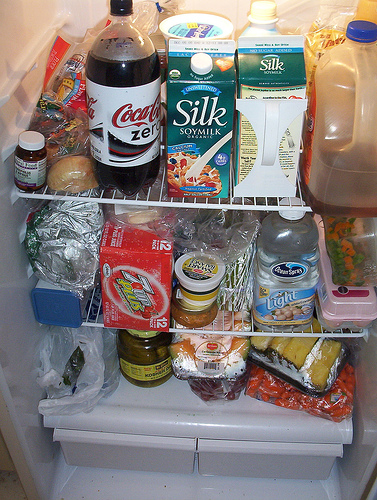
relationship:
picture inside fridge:
[1, 0, 372, 497] [1, 5, 375, 498]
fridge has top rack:
[1, 5, 375, 498] [12, 2, 376, 216]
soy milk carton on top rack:
[161, 33, 238, 208] [12, 2, 376, 216]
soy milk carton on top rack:
[233, 28, 310, 203] [12, 2, 376, 216]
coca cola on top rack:
[82, 0, 164, 197] [12, 2, 376, 216]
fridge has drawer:
[1, 5, 375, 498] [48, 427, 199, 483]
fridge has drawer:
[1, 5, 375, 498] [195, 432, 348, 485]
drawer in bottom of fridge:
[48, 427, 199, 483] [1, 5, 375, 498]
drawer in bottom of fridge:
[195, 432, 348, 485] [1, 5, 375, 498]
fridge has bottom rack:
[1, 5, 375, 498] [27, 324, 366, 449]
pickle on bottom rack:
[114, 327, 178, 392] [27, 324, 366, 449]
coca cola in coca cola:
[85, 47, 163, 196] [82, 0, 164, 197]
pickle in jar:
[114, 327, 178, 392] [114, 327, 176, 389]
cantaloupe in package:
[168, 339, 250, 376] [169, 331, 254, 387]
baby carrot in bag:
[336, 380, 355, 401] [244, 362, 359, 426]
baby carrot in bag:
[256, 385, 279, 401] [244, 362, 359, 426]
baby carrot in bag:
[256, 388, 272, 403] [244, 362, 359, 426]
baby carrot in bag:
[336, 371, 355, 401] [244, 362, 359, 426]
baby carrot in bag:
[270, 385, 285, 407] [244, 362, 359, 426]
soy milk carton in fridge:
[161, 33, 238, 208] [1, 5, 375, 498]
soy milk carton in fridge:
[233, 28, 310, 203] [1, 5, 375, 498]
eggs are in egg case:
[312, 216, 376, 332] [311, 213, 375, 337]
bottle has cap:
[11, 129, 50, 197] [16, 131, 49, 154]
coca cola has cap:
[82, 0, 164, 197] [109, 0, 136, 18]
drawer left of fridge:
[48, 427, 199, 483] [1, 5, 375, 498]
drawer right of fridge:
[195, 432, 348, 485] [1, 5, 375, 498]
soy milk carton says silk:
[161, 33, 238, 208] [172, 93, 233, 130]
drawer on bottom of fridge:
[48, 427, 199, 483] [1, 5, 375, 498]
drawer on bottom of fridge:
[195, 432, 348, 485] [1, 5, 375, 498]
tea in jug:
[299, 163, 376, 223] [298, 16, 376, 221]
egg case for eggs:
[311, 213, 375, 337] [312, 216, 376, 332]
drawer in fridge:
[48, 427, 199, 483] [1, 5, 375, 498]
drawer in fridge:
[195, 432, 348, 485] [1, 5, 375, 498]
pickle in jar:
[114, 327, 173, 391] [114, 327, 176, 389]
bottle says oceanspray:
[247, 202, 320, 335] [270, 263, 310, 279]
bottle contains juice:
[247, 202, 320, 335] [252, 250, 321, 334]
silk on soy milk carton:
[172, 93, 233, 130] [161, 33, 238, 208]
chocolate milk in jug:
[299, 163, 376, 223] [298, 16, 376, 221]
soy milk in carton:
[179, 127, 225, 140] [161, 33, 238, 208]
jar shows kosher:
[114, 327, 176, 389] [144, 366, 168, 380]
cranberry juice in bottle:
[249, 282, 317, 330] [247, 202, 320, 335]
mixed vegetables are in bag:
[323, 216, 374, 285] [320, 215, 376, 297]